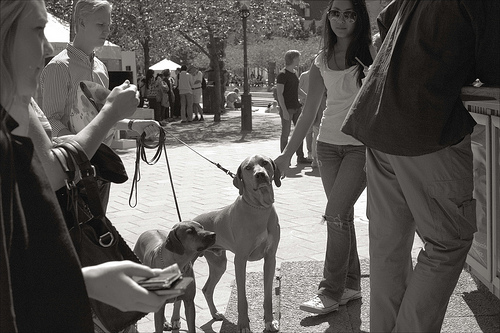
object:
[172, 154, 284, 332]
dog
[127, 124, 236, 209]
leash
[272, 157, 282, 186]
ear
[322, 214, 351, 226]
tear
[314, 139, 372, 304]
jeans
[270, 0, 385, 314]
woman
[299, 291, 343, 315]
shoe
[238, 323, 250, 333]
paw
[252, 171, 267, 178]
nose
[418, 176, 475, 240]
pocket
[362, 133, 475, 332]
jeans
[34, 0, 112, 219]
man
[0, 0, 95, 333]
lady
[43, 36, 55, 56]
nose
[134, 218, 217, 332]
dog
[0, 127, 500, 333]
street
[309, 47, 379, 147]
shirt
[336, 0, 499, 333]
man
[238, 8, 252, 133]
light post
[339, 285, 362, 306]
shoe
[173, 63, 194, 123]
person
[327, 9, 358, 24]
sunglasses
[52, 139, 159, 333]
purse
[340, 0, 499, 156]
shirt